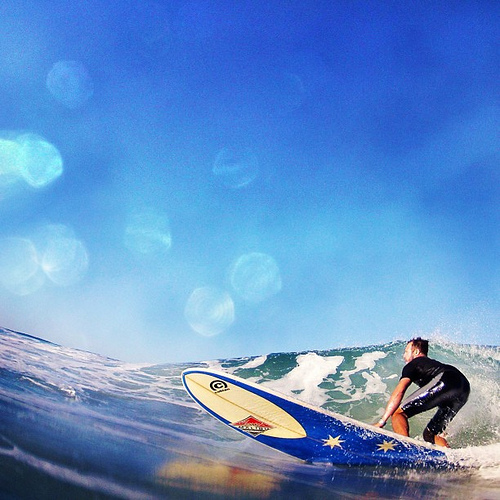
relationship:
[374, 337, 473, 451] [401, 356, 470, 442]
man wearing wetsuit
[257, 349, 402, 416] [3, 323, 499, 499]
foam on ocean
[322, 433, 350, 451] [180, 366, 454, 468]
star on surfboard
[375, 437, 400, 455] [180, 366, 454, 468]
star on surfboard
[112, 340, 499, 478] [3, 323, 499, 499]
wave in ocean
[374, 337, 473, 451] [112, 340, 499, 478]
man riding wave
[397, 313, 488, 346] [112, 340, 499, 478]
splash on wave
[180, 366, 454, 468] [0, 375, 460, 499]
surfboard has reflection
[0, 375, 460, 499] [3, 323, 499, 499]
reflection on ocean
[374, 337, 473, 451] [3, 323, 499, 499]
man surfing ocean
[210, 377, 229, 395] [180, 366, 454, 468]
logo on surfboard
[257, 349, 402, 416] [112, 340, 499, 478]
foam on wave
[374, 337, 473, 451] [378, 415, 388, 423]
man wearing watch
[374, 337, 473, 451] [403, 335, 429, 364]
man has head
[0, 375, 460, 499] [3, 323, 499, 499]
reflection seen on ocean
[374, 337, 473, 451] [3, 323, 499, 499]
man standing in ocean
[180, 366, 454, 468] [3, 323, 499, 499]
surfboard above ocean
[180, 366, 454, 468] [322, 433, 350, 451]
surfboard has star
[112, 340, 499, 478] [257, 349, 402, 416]
wave has foam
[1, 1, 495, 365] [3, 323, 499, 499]
sky above ocean